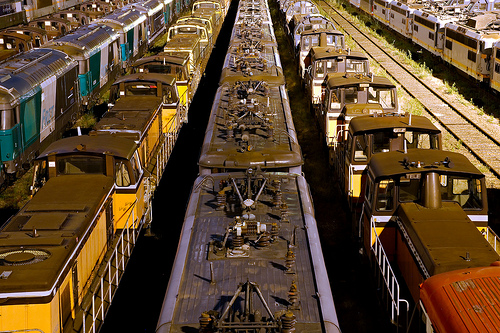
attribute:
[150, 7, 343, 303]
trains — white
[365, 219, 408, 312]
ladder — metal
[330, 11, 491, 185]
tracks — empty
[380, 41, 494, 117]
grass — green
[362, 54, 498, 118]
rail — edged, metal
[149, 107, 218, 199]
fence — metal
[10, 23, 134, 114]
train — silver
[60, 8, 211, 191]
train — yellow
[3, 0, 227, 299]
trains — yellow, blue, orange, rusty, metal